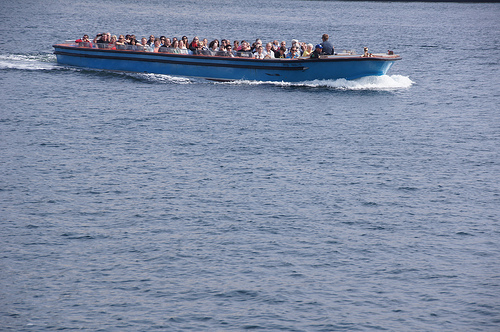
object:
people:
[263, 42, 275, 62]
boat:
[51, 39, 403, 86]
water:
[0, 1, 500, 331]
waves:
[0, 50, 53, 70]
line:
[52, 50, 310, 76]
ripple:
[98, 167, 227, 230]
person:
[311, 44, 327, 58]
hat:
[313, 51, 322, 52]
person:
[81, 33, 90, 48]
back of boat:
[53, 33, 121, 72]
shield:
[51, 45, 313, 74]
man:
[317, 33, 336, 54]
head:
[320, 35, 330, 43]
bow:
[367, 50, 405, 69]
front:
[338, 51, 403, 87]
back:
[53, 44, 113, 68]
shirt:
[259, 48, 274, 57]